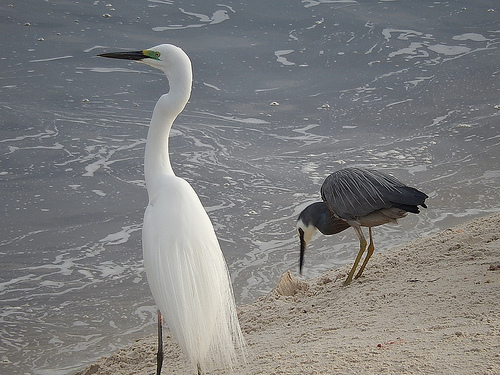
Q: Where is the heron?
A: At the water's edge.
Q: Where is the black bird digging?
A: In the sand.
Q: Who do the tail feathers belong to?
A: The heron.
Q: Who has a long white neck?
A: The heron.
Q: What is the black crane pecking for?
A: Bugs.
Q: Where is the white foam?
A: On top of the water.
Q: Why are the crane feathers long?
A: They need them long to fly.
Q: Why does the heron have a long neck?
A: To catch fish.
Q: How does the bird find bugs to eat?
A: By pecking in the sand.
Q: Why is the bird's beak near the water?
A: Looking for fish.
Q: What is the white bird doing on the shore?
A: Looking across the sea.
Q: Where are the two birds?
A: Seashore.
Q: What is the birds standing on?
A: Sand.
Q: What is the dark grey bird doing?
A: Drinking water.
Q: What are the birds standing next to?
A: A gray body of water.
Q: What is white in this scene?
A: A large bird.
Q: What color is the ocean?
A: Grey.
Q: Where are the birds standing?
A: On the beach.